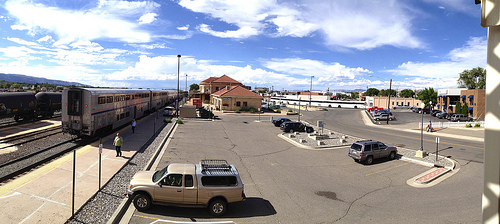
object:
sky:
[0, 0, 500, 89]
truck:
[118, 157, 251, 217]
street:
[130, 111, 500, 224]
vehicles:
[371, 113, 396, 122]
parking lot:
[366, 105, 477, 124]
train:
[54, 85, 188, 138]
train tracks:
[0, 126, 64, 184]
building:
[253, 85, 272, 94]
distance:
[237, 79, 476, 96]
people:
[110, 131, 127, 158]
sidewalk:
[64, 124, 130, 224]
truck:
[346, 137, 400, 166]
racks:
[198, 156, 234, 174]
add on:
[198, 156, 247, 186]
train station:
[0, 72, 500, 224]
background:
[0, 78, 67, 100]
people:
[125, 118, 140, 135]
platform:
[77, 116, 151, 179]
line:
[157, 217, 236, 223]